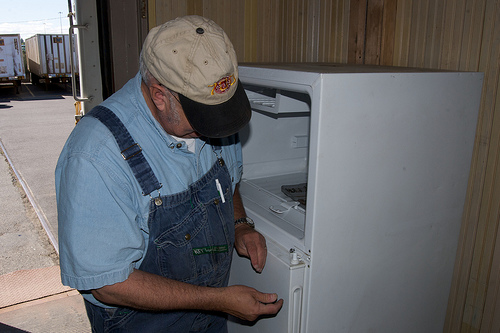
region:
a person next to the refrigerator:
[47, 12, 487, 330]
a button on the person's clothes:
[153, 194, 163, 206]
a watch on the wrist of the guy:
[231, 215, 254, 228]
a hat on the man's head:
[138, 12, 255, 142]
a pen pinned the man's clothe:
[212, 176, 226, 205]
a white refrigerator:
[234, 57, 490, 331]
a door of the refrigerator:
[228, 216, 308, 331]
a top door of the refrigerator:
[235, 75, 309, 246]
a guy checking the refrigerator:
[46, 11, 487, 331]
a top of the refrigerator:
[234, 56, 482, 73]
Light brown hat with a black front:
[140, 17, 252, 142]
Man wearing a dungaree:
[53, 101, 242, 331]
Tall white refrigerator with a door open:
[196, 56, 481, 331]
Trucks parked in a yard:
[0, 30, 73, 105]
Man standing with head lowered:
[46, 50, 287, 330]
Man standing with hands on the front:
[45, 50, 297, 330]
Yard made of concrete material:
[0, 91, 95, 327]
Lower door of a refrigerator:
[195, 210, 310, 330]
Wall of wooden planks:
[131, 2, 496, 328]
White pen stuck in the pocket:
[210, 173, 239, 251]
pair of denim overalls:
[70, 95, 249, 331]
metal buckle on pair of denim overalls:
[134, 173, 176, 213]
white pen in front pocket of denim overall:
[208, 175, 230, 207]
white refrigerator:
[220, 48, 492, 329]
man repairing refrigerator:
[50, 11, 489, 331]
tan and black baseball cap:
[130, 14, 261, 147]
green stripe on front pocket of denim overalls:
[184, 238, 234, 260]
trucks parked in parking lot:
[0, 24, 77, 111]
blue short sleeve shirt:
[35, 68, 272, 313]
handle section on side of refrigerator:
[282, 278, 310, 332]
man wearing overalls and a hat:
[39, 20, 289, 330]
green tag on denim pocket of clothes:
[179, 237, 243, 272]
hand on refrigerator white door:
[223, 270, 320, 325]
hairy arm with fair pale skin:
[128, 267, 230, 324]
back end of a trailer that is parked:
[20, 15, 85, 105]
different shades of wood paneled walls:
[293, 5, 430, 61]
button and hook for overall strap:
[130, 179, 177, 219]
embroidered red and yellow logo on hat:
[195, 71, 239, 107]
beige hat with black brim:
[167, 79, 271, 140]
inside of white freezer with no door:
[229, 56, 322, 259]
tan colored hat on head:
[143, 17, 235, 107]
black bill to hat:
[188, 92, 254, 137]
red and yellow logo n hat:
[196, 69, 237, 96]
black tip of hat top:
[186, 23, 202, 40]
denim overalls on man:
[92, 171, 259, 331]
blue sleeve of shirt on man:
[42, 139, 141, 288]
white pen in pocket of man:
[207, 174, 233, 210]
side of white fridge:
[295, 64, 485, 323]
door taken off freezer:
[253, 82, 314, 235]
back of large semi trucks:
[30, 33, 87, 90]